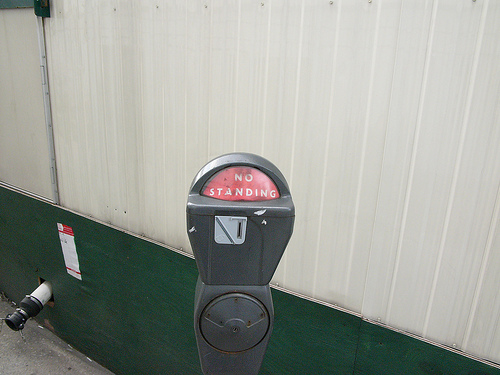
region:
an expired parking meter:
[147, 129, 331, 373]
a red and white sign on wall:
[45, 218, 101, 290]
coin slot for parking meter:
[211, 206, 245, 254]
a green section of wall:
[4, 185, 385, 374]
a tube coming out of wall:
[4, 279, 56, 335]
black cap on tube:
[2, 296, 58, 347]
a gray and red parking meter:
[160, 145, 305, 369]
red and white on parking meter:
[205, 169, 277, 204]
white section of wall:
[11, 0, 496, 307]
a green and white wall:
[7, 6, 472, 373]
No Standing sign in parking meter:
[196, 162, 284, 203]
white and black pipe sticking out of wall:
[7, 268, 57, 338]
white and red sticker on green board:
[52, 217, 83, 278]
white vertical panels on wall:
[0, 0, 499, 372]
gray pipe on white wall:
[31, 5, 66, 205]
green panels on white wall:
[0, 0, 55, 20]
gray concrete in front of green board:
[0, 293, 115, 373]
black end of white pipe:
[3, 282, 52, 329]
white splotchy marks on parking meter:
[185, 188, 274, 237]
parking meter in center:
[154, 132, 321, 334]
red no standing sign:
[202, 162, 293, 209]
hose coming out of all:
[14, 277, 43, 333]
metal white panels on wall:
[323, 172, 470, 254]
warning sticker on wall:
[55, 210, 93, 289]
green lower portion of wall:
[98, 264, 182, 360]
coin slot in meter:
[223, 214, 250, 242]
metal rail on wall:
[32, 15, 72, 190]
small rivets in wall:
[110, 1, 127, 28]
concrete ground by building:
[15, 321, 52, 369]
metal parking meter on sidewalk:
[163, 133, 318, 373]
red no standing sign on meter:
[192, 143, 302, 224]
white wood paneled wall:
[335, 80, 439, 298]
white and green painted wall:
[6, 173, 211, 368]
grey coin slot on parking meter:
[207, 209, 254, 256]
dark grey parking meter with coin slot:
[173, 131, 301, 373]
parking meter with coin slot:
[212, 212, 254, 252]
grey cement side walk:
[11, 345, 61, 373]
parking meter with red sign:
[182, 143, 302, 368]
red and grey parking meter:
[177, 141, 295, 356]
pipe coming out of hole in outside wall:
[3, 274, 57, 331]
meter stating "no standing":
[184, 151, 296, 373]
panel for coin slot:
[213, 215, 248, 245]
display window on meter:
[196, 163, 283, 203]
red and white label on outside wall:
[56, 221, 83, 280]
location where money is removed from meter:
[197, 290, 272, 356]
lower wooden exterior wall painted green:
[0, 181, 499, 373]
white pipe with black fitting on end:
[4, 278, 55, 335]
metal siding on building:
[0, 0, 498, 370]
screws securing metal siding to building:
[110, 0, 499, 13]